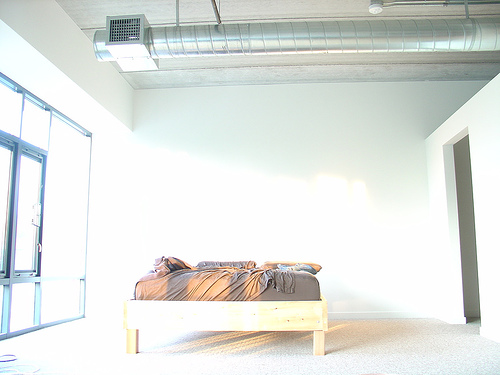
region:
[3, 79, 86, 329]
it is a window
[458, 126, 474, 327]
it is a door in the room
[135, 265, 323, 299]
it is a double bed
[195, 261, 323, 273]
it is a pillow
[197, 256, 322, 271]
two pillows are visible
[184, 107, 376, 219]
it is a white color wall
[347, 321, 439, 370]
it is a white color ground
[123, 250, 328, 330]
this is a bed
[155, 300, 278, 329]
the bed is wooden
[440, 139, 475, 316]
this is a door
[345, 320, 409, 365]
this is the floor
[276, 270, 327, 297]
this is a mattress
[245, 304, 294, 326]
the bed is brown in colour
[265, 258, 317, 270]
this is a pillow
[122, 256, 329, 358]
a bed in a room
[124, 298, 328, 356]
the frame is wood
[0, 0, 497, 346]
the walls are white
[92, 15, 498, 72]
an air conditioning tunnel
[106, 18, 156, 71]
the box is silver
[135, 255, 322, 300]
blanket is brown and orange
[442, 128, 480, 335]
an open door way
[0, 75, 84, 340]
window to the outside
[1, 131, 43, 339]
the door is closed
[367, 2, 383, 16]
light on the ceiling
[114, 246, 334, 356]
a bed of wood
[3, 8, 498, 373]
a bed in a white room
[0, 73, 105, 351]
a large window in a room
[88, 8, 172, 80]
a vent in a pipe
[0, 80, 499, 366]
the wall of room is white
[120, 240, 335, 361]
a mattress color brown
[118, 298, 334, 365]
a bed color brown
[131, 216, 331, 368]
a bed with wooden frame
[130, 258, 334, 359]
Platform bed in the room.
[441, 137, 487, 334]
doorway leading out of the room.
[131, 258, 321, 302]
orange and brown bed sheets.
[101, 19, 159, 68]
air vent above the bed in the room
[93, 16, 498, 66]
metal pipe above the bedroom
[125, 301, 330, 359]
light wood bedframe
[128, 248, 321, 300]
two pillows on the bed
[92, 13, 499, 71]
Ventilation ducting above the bed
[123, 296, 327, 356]
Pine bed frame in the middle of the room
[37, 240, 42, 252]
Latch to lock the window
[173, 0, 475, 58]
Metal strapping holding the ducting to the ceiling